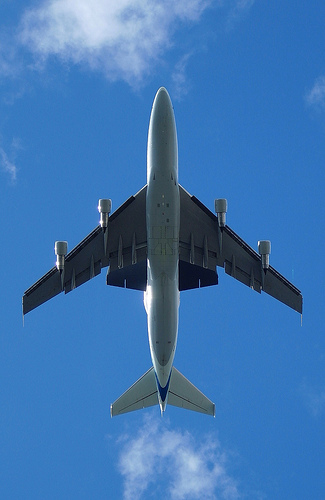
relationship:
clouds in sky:
[305, 73, 324, 100] [1, 0, 324, 498]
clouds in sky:
[305, 76, 324, 107] [1, 0, 324, 498]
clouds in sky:
[0, 148, 19, 178] [1, 0, 324, 498]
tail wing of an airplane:
[161, 360, 216, 420] [18, 80, 307, 428]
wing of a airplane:
[178, 183, 302, 313] [22, 82, 305, 420]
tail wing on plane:
[19, 183, 148, 317] [45, 81, 309, 333]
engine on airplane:
[53, 238, 68, 270] [18, 80, 307, 428]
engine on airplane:
[96, 195, 113, 236] [18, 80, 307, 428]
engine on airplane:
[212, 196, 229, 230] [18, 80, 307, 428]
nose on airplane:
[151, 85, 171, 105] [22, 82, 305, 420]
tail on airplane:
[155, 382, 170, 414] [22, 82, 305, 420]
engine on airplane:
[211, 193, 230, 229] [22, 82, 305, 420]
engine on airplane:
[53, 238, 68, 277] [22, 82, 305, 420]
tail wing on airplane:
[19, 183, 148, 317] [22, 82, 305, 420]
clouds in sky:
[105, 403, 239, 498] [1, 0, 324, 498]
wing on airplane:
[178, 183, 302, 313] [22, 82, 305, 420]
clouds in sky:
[118, 416, 239, 498] [1, 0, 324, 498]